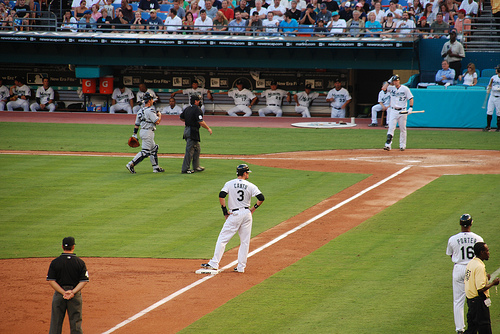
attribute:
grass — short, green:
[3, 122, 495, 332]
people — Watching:
[101, 5, 443, 35]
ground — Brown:
[0, 120, 500, 329]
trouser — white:
[206, 206, 252, 269]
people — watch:
[7, 0, 461, 39]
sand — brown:
[249, 148, 496, 176]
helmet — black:
[235, 161, 250, 175]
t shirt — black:
[46, 249, 88, 292]